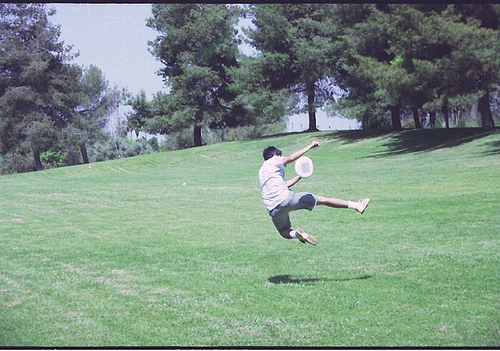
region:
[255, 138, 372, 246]
boy jumping to catch a frisbee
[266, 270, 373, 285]
shadow cast by boy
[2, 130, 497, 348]
green grass on field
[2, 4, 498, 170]
green leaves on trees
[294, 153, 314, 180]
white frisbee in air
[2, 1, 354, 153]
clear blue cloudless sky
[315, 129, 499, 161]
shadows cast by trees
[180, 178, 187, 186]
small white ball laying in grass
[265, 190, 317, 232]
light blue denim shorts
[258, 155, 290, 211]
short sleeve white shirt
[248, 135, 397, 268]
a kid catching a frisbee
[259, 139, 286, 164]
the head of a young boy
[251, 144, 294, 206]
the torso of a young boy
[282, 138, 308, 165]
the arm of a young boy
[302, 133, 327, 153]
the hand of a young boy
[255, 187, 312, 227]
the shorts of a young boy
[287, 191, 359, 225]
the leg of a young boy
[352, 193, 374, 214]
the feet of a young boy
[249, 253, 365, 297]
the shadow of a young boy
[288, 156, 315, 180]
a small white toy frisbee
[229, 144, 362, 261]
person in the air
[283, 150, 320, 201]
disc is white and round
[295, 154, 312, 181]
disc is in the air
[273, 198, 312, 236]
person has blue shorts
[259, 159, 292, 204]
white shirt on the male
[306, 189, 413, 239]
right leg is outstrectched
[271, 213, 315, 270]
left knee is bent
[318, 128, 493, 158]
shadows from the trees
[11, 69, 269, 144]
trees on a hill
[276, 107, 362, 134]
white house in between trees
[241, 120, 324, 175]
a boy in the air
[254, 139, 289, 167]
the head of a boy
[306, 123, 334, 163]
the hand of a boy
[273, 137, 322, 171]
the arm of a boy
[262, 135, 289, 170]
the hair of a boy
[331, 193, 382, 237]
the foot of a boy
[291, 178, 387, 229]
the leg of a boy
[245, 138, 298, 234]
the back of a boy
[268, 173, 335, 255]
a boy wearing pants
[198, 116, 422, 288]
a boy in a field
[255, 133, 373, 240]
a man leaping to catch a frisbee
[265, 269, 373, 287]
the shadow of a man on the grass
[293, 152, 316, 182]
a white frisbee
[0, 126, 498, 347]
a green grassy field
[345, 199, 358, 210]
a white sock on a man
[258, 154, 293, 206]
a white shirt on a man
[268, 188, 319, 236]
jean shorts on a man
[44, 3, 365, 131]
a pale blue sky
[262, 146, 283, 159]
dark hair on a man's head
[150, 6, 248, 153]
a tree on the edge of a field